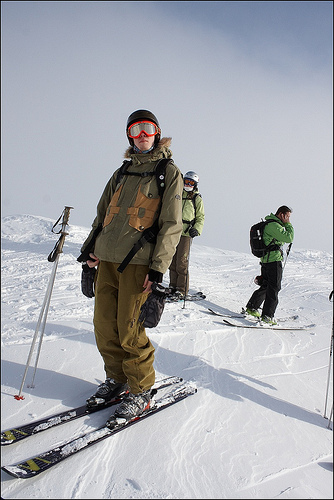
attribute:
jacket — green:
[249, 207, 299, 265]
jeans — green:
[86, 262, 160, 392]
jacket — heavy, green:
[260, 213, 291, 258]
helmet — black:
[124, 106, 158, 153]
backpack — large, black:
[252, 216, 283, 256]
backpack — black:
[245, 215, 284, 260]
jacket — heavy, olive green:
[75, 147, 199, 269]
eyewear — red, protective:
[125, 113, 158, 143]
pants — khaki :
[54, 256, 187, 383]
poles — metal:
[10, 202, 74, 399]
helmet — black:
[111, 104, 166, 128]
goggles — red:
[108, 111, 165, 148]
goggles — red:
[126, 119, 161, 141]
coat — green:
[257, 214, 295, 264]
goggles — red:
[117, 122, 179, 139]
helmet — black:
[116, 104, 171, 126]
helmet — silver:
[184, 171, 198, 190]